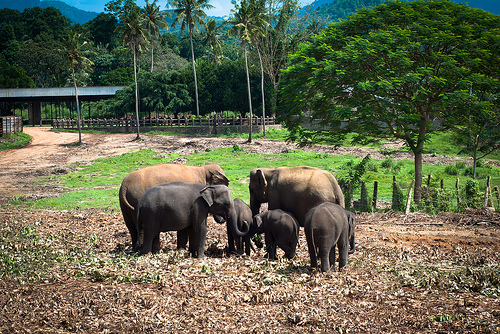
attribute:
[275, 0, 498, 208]
tree — green, tall, leafy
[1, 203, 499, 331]
foliage — dead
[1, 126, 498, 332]
ground — brown, green, dry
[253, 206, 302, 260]
elephant — baby, brown, dark, grey, grouped, family, gathered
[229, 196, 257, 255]
elephant — baby, brown, dark, grey, grouped, family, gathered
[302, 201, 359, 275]
elephant — baby, brown, grey, grouped, family, gathered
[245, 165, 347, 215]
elephant — grouped, adult, brown, large, gathered, family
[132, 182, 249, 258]
elephant — grouped, adult, brown, grey, family, gathered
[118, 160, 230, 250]
elephant — grouped, adult, brown, large, family, gathered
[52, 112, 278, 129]
fence — containing, brown, wooden, concrete, old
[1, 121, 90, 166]
road — dirt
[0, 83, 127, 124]
enclosure — roofed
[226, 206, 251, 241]
trunk — curled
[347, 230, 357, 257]
trunk — curled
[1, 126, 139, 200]
dirt — brown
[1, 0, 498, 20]
sky — blue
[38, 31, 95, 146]
tree — palm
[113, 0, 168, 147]
tree — palm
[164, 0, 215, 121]
tree — palm